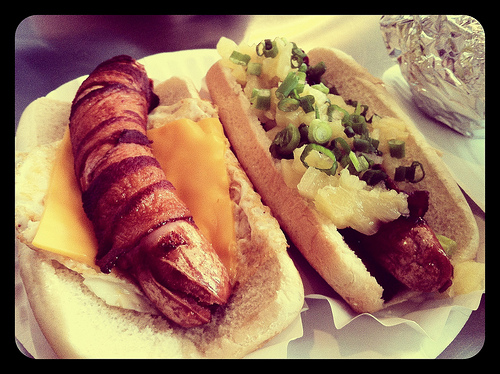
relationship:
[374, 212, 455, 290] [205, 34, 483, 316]
ketchup on hot dog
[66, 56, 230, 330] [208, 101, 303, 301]
bacon wrapped  on bun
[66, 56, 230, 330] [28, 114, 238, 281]
bacon wrapped  sausage on cheese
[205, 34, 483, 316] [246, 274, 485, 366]
hot dog on paper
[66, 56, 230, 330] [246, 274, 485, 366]
bacon on paper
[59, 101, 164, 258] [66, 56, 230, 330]
bacon on a bacon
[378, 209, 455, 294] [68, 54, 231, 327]
tip of a sausage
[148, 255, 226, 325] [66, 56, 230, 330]
split on bacon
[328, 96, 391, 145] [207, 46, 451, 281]
slice on hot dog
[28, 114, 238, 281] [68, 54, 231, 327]
cheese on sausage